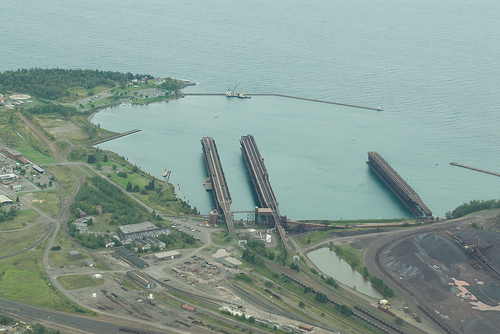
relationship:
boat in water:
[228, 89, 253, 111] [251, 103, 370, 180]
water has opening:
[251, 103, 370, 180] [376, 107, 433, 158]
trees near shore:
[33, 75, 62, 97] [63, 66, 180, 80]